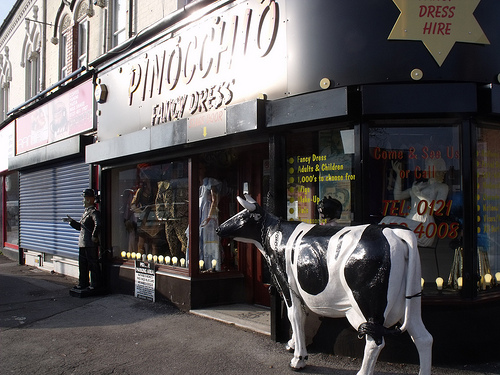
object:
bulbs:
[120, 250, 218, 269]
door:
[284, 142, 350, 227]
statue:
[61, 188, 102, 298]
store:
[83, 0, 500, 353]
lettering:
[287, 150, 355, 225]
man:
[62, 188, 103, 290]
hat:
[81, 189, 95, 197]